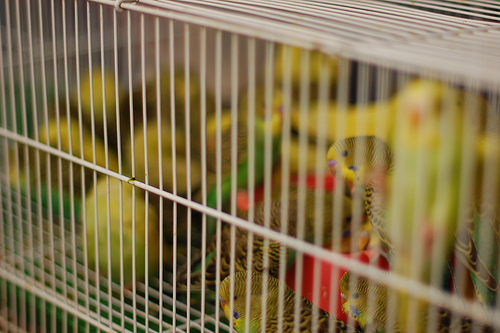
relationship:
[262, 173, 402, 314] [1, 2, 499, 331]
dish in cage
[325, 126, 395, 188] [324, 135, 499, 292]
head of bird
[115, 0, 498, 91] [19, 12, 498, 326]
top of bird cage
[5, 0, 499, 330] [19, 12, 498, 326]
side of bird cage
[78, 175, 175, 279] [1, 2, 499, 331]
bird in cage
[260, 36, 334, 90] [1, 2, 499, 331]
birds in cage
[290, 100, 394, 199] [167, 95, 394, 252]
bird in cage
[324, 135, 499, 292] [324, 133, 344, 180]
bird has yellow beak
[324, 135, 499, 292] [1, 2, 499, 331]
bird in cage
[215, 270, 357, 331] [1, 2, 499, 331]
bird in cage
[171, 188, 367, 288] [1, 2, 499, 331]
bird in cage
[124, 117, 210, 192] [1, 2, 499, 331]
bird in cage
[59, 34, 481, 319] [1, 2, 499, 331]
birds in cage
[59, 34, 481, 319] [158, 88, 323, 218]
birds in cage